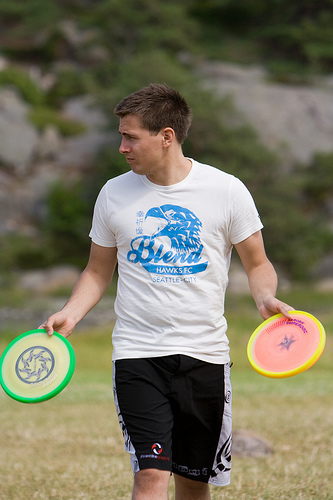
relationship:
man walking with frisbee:
[38, 84, 296, 500] [0, 328, 76, 403]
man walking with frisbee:
[38, 84, 296, 500] [246, 310, 326, 379]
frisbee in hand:
[246, 310, 326, 379] [257, 297, 298, 323]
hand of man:
[257, 297, 298, 323] [38, 84, 296, 500]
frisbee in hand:
[0, 328, 76, 403] [38, 312, 76, 339]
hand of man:
[38, 312, 76, 339] [38, 84, 296, 500]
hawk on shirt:
[144, 205, 203, 250] [88, 157, 262, 367]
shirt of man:
[88, 157, 262, 367] [38, 84, 296, 500]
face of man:
[117, 115, 148, 176] [38, 84, 296, 500]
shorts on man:
[112, 353, 233, 488] [38, 84, 296, 500]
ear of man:
[162, 127, 175, 149] [38, 84, 296, 500]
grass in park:
[0, 294, 331, 499] [0, 1, 332, 499]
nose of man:
[118, 138, 131, 155] [38, 84, 296, 500]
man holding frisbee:
[38, 84, 296, 500] [0, 328, 76, 403]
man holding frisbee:
[38, 84, 296, 500] [246, 310, 326, 379]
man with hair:
[38, 84, 296, 500] [114, 82, 192, 145]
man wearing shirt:
[38, 84, 296, 500] [88, 157, 262, 367]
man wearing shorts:
[38, 84, 296, 500] [112, 353, 233, 488]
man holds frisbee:
[38, 84, 296, 500] [0, 328, 76, 403]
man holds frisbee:
[38, 84, 296, 500] [246, 310, 326, 379]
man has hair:
[38, 84, 296, 500] [114, 82, 192, 145]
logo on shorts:
[152, 442, 162, 456] [112, 353, 233, 488]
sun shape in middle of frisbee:
[18, 348, 53, 384] [0, 328, 76, 403]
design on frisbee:
[277, 336, 296, 352] [246, 310, 326, 379]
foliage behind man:
[0, 1, 331, 278] [38, 84, 296, 500]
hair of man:
[114, 82, 192, 145] [38, 84, 296, 500]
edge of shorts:
[133, 459, 174, 474] [112, 353, 233, 488]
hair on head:
[114, 82, 192, 145] [120, 84, 192, 175]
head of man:
[120, 84, 192, 175] [38, 84, 296, 500]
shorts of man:
[112, 353, 233, 488] [38, 84, 296, 500]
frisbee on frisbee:
[0, 328, 76, 403] [0, 328, 76, 403]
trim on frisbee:
[246, 310, 327, 380] [246, 310, 326, 379]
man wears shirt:
[38, 84, 296, 500] [88, 157, 262, 367]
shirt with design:
[88, 157, 262, 367] [127, 203, 208, 275]